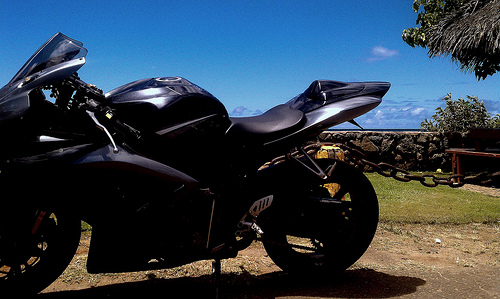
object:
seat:
[224, 103, 305, 140]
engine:
[3, 23, 399, 298]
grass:
[370, 174, 498, 223]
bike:
[3, 22, 398, 297]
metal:
[233, 180, 289, 242]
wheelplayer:
[259, 157, 379, 275]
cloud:
[373, 46, 397, 58]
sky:
[117, 6, 419, 75]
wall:
[327, 125, 447, 171]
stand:
[202, 235, 233, 296]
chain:
[354, 135, 431, 187]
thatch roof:
[427, 2, 499, 59]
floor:
[384, 226, 480, 286]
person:
[371, 217, 460, 273]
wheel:
[250, 188, 388, 284]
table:
[448, 143, 496, 178]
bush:
[419, 92, 499, 128]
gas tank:
[109, 72, 236, 153]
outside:
[120, 9, 418, 124]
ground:
[384, 208, 497, 296]